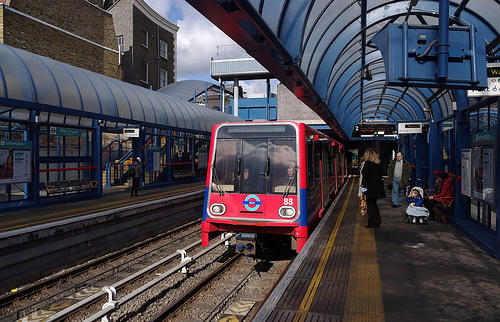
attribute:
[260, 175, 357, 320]
bricks — red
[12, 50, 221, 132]
glass — clean, clear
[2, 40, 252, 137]
glass — clean, clear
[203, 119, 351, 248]
train — red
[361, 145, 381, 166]
hair — blonde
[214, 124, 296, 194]
glass — clear, clean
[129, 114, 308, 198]
glass — clear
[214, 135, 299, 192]
windshield — glass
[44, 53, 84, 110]
glass — clear, clean